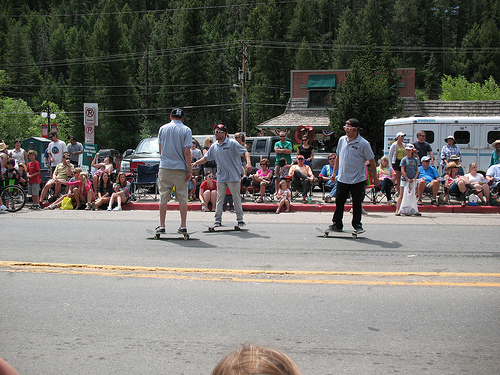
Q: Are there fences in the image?
A: No, there are no fences.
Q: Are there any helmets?
A: No, there are no helmets.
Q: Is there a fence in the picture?
A: No, there are no fences.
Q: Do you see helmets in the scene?
A: No, there are no helmets.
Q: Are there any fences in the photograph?
A: No, there are no fences.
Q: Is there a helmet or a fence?
A: No, there are no fences or helmets.